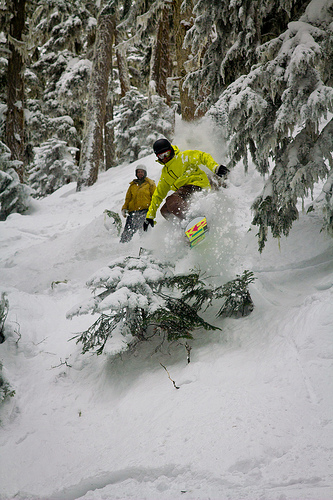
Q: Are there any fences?
A: No, there are no fences.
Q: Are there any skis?
A: No, there are no skis.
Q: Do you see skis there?
A: No, there are no skis.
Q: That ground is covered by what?
A: The ground is covered by the snow.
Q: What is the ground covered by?
A: The ground is covered by the snow.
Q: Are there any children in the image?
A: No, there are no children.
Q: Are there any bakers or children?
A: No, there are no children or bakers.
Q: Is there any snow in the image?
A: Yes, there is snow.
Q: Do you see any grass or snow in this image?
A: Yes, there is snow.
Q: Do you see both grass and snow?
A: No, there is snow but no grass.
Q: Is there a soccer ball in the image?
A: No, there are no soccer balls.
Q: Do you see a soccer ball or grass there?
A: No, there are no soccer balls or grass.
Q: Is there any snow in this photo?
A: Yes, there is snow.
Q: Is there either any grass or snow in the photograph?
A: Yes, there is snow.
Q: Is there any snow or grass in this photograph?
A: Yes, there is snow.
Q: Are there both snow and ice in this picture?
A: No, there is snow but no ice.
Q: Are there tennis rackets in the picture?
A: No, there are no tennis rackets.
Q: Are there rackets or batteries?
A: No, there are no rackets or batteries.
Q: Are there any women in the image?
A: No, there are no women.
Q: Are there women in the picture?
A: No, there are no women.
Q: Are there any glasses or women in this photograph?
A: No, there are no women or glasses.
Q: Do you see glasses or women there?
A: No, there are no women or glasses.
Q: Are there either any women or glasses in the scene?
A: No, there are no women or glasses.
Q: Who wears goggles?
A: The man wears goggles.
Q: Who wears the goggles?
A: The man wears goggles.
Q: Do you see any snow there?
A: Yes, there is snow.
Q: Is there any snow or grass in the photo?
A: Yes, there is snow.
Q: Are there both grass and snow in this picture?
A: No, there is snow but no grass.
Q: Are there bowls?
A: No, there are no bowls.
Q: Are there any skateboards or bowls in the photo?
A: No, there are no bowls or skateboards.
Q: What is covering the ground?
A: The snow is covering the ground.